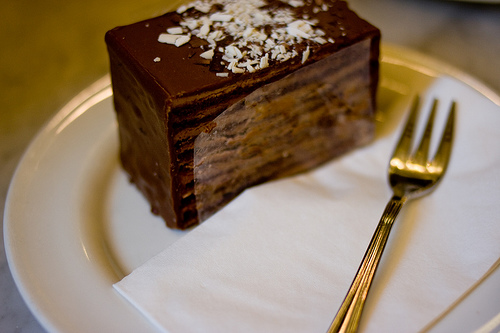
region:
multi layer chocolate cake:
[94, 1, 381, 233]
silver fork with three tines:
[319, 91, 454, 332]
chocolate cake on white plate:
[96, 2, 380, 291]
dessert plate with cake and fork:
[8, 2, 498, 332]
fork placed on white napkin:
[109, 73, 479, 331]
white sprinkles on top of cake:
[155, 2, 348, 79]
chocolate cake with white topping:
[98, 1, 383, 231]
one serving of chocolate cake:
[101, 1, 382, 236]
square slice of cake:
[102, 0, 383, 234]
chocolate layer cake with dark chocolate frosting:
[103, 2, 385, 237]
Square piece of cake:
[102, 0, 383, 226]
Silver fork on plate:
[316, 99, 456, 331]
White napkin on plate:
[113, 75, 498, 331]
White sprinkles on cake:
[160, 1, 339, 71]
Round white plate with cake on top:
[3, 41, 498, 331]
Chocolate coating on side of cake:
[100, 38, 180, 228]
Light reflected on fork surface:
[390, 157, 442, 174]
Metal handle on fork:
[332, 188, 397, 331]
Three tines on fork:
[387, 92, 457, 190]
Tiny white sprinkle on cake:
[151, 53, 163, 65]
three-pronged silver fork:
[328, 93, 459, 331]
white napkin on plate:
[112, 76, 497, 331]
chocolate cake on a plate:
[103, 0, 382, 231]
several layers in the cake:
[168, 38, 377, 223]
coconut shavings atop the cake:
[159, 1, 331, 74]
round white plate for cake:
[1, 42, 498, 332]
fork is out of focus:
[323, 91, 461, 331]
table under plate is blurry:
[2, 3, 171, 193]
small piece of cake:
[100, 0, 382, 232]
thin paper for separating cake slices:
[192, 37, 381, 216]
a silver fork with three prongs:
[320, 86, 468, 332]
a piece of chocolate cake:
[97, 0, 384, 227]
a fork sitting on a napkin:
[107, 75, 494, 330]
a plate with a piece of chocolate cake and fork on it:
[0, 1, 496, 329]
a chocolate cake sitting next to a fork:
[100, 2, 465, 332]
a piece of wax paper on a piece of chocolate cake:
[173, 35, 383, 223]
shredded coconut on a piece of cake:
[155, 1, 340, 80]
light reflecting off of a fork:
[385, 152, 452, 188]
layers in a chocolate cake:
[157, 31, 390, 221]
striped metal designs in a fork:
[318, 186, 407, 328]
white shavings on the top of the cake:
[168, 3, 314, 66]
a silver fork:
[335, 92, 455, 327]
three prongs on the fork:
[387, 90, 452, 190]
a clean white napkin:
[115, 80, 495, 325]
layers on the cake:
[202, 70, 344, 182]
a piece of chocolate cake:
[105, 2, 381, 219]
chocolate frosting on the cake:
[114, 28, 190, 110]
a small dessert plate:
[11, 38, 478, 331]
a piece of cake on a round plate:
[8, 6, 496, 331]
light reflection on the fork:
[387, 159, 444, 174]